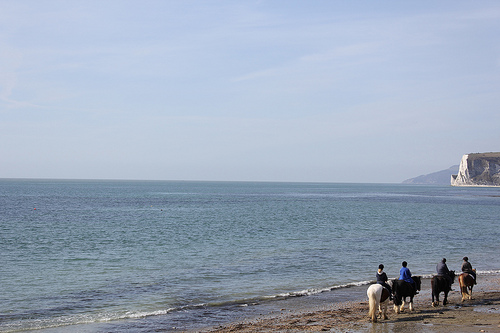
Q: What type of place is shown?
A: It is an ocean.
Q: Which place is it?
A: It is an ocean.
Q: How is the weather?
A: It is clear.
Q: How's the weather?
A: It is clear.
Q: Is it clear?
A: Yes, it is clear.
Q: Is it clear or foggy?
A: It is clear.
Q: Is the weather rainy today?
A: No, it is clear.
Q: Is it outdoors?
A: Yes, it is outdoors.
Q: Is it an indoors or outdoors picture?
A: It is outdoors.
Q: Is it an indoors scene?
A: No, it is outdoors.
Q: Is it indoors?
A: No, it is outdoors.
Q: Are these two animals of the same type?
A: Yes, all the animals are horses.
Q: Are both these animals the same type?
A: Yes, all the animals are horses.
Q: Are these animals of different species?
A: No, all the animals are horses.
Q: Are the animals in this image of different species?
A: No, all the animals are horses.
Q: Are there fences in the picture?
A: No, there are no fences.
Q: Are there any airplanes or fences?
A: No, there are no fences or airplanes.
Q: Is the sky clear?
A: Yes, the sky is clear.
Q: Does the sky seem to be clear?
A: Yes, the sky is clear.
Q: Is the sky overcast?
A: No, the sky is clear.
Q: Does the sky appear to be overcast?
A: No, the sky is clear.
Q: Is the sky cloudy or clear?
A: The sky is clear.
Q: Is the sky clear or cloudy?
A: The sky is clear.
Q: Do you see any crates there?
A: No, there are no crates.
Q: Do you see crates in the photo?
A: No, there are no crates.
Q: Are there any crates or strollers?
A: No, there are no crates or strollers.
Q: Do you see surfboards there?
A: No, there are no surfboards.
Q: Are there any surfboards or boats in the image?
A: No, there are no surfboards or boats.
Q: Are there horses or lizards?
A: Yes, there is a horse.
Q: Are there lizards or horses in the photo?
A: Yes, there is a horse.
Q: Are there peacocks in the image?
A: No, there are no peacocks.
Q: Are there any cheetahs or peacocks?
A: No, there are no peacocks or cheetahs.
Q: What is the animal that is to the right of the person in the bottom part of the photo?
A: The animal is a horse.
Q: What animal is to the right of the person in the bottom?
A: The animal is a horse.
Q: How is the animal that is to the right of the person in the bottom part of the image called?
A: The animal is a horse.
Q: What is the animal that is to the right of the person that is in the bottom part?
A: The animal is a horse.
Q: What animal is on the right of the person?
A: The animal is a horse.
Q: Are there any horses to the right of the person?
A: Yes, there is a horse to the right of the person.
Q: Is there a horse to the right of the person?
A: Yes, there is a horse to the right of the person.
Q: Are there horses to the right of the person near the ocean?
A: Yes, there is a horse to the right of the person.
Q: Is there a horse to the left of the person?
A: No, the horse is to the right of the person.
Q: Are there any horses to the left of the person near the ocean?
A: No, the horse is to the right of the person.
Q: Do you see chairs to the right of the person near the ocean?
A: No, there is a horse to the right of the person.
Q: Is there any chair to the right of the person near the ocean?
A: No, there is a horse to the right of the person.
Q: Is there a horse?
A: Yes, there is a horse.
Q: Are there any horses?
A: Yes, there is a horse.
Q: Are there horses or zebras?
A: Yes, there is a horse.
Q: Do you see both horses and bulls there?
A: No, there is a horse but no bulls.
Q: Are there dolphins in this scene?
A: No, there are no dolphins.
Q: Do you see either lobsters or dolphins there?
A: No, there are no dolphins or lobsters.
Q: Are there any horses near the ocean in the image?
A: Yes, there is a horse near the ocean.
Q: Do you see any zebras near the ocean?
A: No, there is a horse near the ocean.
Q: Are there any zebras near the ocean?
A: No, there is a horse near the ocean.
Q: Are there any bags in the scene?
A: No, there are no bags.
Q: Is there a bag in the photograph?
A: No, there are no bags.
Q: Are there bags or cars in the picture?
A: No, there are no bags or cars.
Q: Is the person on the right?
A: Yes, the person is on the right of the image.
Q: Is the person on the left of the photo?
A: No, the person is on the right of the image.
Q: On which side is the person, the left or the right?
A: The person is on the right of the image.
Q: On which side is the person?
A: The person is on the right of the image.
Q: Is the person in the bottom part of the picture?
A: Yes, the person is in the bottom of the image.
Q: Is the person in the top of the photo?
A: No, the person is in the bottom of the image.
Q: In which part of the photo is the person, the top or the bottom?
A: The person is in the bottom of the image.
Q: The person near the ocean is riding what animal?
A: The person is riding a horse.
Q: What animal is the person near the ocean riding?
A: The person is riding a horse.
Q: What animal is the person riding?
A: The person is riding a horse.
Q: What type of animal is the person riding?
A: The person is riding a horse.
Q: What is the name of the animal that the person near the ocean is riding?
A: The animal is a horse.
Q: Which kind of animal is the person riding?
A: The person is riding a horse.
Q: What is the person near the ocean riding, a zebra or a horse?
A: The person is riding a horse.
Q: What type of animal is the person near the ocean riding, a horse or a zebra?
A: The person is riding a horse.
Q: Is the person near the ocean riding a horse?
A: Yes, the person is riding a horse.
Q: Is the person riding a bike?
A: No, the person is riding a horse.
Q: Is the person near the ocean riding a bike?
A: No, the person is riding a horse.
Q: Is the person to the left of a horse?
A: Yes, the person is to the left of a horse.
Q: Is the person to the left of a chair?
A: No, the person is to the left of a horse.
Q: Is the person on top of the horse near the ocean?
A: Yes, the person is on top of the horse.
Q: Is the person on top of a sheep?
A: No, the person is on top of the horse.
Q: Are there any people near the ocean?
A: Yes, there is a person near the ocean.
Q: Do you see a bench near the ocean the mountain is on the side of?
A: No, there is a person near the ocean.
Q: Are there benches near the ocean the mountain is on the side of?
A: No, there is a person near the ocean.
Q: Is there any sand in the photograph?
A: Yes, there is sand.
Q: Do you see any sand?
A: Yes, there is sand.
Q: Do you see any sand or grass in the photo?
A: Yes, there is sand.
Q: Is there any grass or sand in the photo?
A: Yes, there is sand.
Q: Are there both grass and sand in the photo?
A: No, there is sand but no grass.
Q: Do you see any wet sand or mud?
A: Yes, there is wet sand.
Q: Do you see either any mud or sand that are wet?
A: Yes, the sand is wet.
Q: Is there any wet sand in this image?
A: Yes, there is wet sand.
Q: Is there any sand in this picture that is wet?
A: Yes, there is sand that is wet.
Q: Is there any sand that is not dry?
A: Yes, there is wet sand.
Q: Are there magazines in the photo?
A: No, there are no magazines.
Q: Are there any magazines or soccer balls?
A: No, there are no magazines or soccer balls.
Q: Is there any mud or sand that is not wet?
A: No, there is sand but it is wet.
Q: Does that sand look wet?
A: Yes, the sand is wet.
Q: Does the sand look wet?
A: Yes, the sand is wet.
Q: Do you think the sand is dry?
A: No, the sand is wet.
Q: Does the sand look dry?
A: No, the sand is wet.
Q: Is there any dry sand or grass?
A: No, there is sand but it is wet.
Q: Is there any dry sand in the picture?
A: No, there is sand but it is wet.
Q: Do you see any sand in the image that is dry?
A: No, there is sand but it is wet.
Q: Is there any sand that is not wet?
A: No, there is sand but it is wet.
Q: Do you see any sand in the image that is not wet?
A: No, there is sand but it is wet.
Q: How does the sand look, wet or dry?
A: The sand is wet.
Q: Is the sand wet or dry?
A: The sand is wet.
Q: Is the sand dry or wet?
A: The sand is wet.